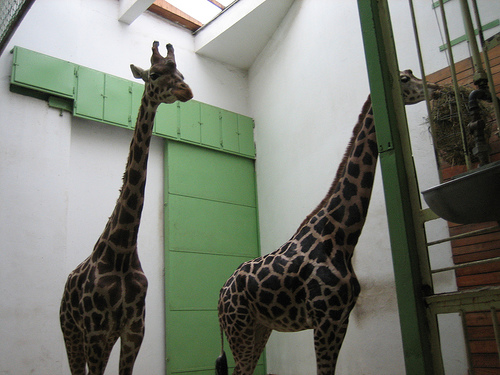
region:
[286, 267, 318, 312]
giraffe has dark spots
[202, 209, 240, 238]
green panel behind giraffe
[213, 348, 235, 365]
tuft on giraffes tail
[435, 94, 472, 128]
giraffe is eating hay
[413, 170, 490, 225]
dark bowl with water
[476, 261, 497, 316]
brown wood paneling on wall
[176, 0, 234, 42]
sky light in white ceiling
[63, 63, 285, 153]
green cabinets in pen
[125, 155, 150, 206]
giraffe has short dark mane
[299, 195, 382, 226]
giraffe has rough dry mane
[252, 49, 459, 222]
the giraffe is eating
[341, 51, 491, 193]
the giraffe is eating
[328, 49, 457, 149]
the giraffe is eating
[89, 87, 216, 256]
giraffes have long necks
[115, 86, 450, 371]
giraffes have long necks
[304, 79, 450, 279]
giraffes have long necks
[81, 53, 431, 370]
Giraffes in the room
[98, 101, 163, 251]
The giraffe has a long neck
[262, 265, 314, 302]
The giraffe has spots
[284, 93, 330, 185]
A white wall near the giraffes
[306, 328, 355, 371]
The front legs of the giraffe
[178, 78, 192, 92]
The nose of the giraffe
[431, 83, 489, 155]
Hay for the giraffe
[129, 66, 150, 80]
The right ear of the giraffe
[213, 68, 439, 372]
This giraffe is eating hay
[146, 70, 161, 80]
The eye of the giraffe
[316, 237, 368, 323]
part of a chest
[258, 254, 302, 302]
part of a stomach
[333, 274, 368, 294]
part of a chest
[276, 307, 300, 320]
edge of a stomach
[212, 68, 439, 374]
Giraffe eating dry hay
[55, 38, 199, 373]
Giraffe next to giraffe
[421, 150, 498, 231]
Water basin by hay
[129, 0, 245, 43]
Skylight above tall giraffe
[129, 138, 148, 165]
Large brown spot on giraffe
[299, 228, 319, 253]
Large brown spot on giraffe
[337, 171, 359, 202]
Large brown spot on giraffe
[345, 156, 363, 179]
Large brown spot on giraffe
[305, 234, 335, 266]
Large brown spot on giraffe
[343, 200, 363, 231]
Large brown spot on giraffe